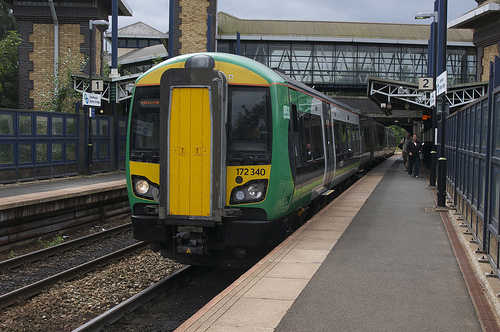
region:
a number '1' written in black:
[236, 168, 241, 175]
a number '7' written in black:
[238, 166, 244, 174]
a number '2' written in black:
[242, 166, 249, 175]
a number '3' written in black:
[249, 167, 255, 179]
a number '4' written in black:
[255, 168, 260, 178]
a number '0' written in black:
[261, 169, 267, 177]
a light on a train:
[228, 176, 271, 210]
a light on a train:
[126, 169, 163, 199]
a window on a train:
[223, 86, 273, 167]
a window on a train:
[129, 88, 159, 159]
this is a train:
[92, 72, 316, 161]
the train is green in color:
[271, 82, 292, 212]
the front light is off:
[228, 180, 264, 208]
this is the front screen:
[238, 93, 268, 150]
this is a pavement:
[388, 227, 435, 311]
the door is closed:
[321, 105, 327, 190]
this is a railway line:
[42, 226, 97, 321]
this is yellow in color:
[151, 90, 206, 261]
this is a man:
[405, 135, 420, 171]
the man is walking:
[403, 132, 421, 176]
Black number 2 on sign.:
[410, 66, 432, 102]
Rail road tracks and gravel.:
[1, 224, 138, 329]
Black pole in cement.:
[418, 144, 470, 235]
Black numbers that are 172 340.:
[222, 159, 274, 183]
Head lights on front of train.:
[101, 176, 278, 208]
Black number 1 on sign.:
[72, 68, 114, 97]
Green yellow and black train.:
[86, 55, 365, 263]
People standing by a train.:
[283, 125, 435, 197]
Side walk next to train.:
[240, 167, 435, 330]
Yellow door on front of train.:
[156, 102, 221, 224]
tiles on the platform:
[228, 287, 325, 329]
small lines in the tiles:
[216, 278, 282, 311]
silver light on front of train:
[234, 171, 288, 210]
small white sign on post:
[394, 71, 464, 102]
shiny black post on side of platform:
[421, 85, 477, 214]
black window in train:
[218, 73, 288, 202]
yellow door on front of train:
[152, 75, 247, 240]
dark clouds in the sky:
[276, 6, 376, 25]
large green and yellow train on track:
[86, 33, 375, 234]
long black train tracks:
[30, 198, 245, 329]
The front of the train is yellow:
[106, 42, 292, 234]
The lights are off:
[106, 161, 227, 233]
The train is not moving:
[87, 66, 244, 305]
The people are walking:
[375, 123, 484, 206]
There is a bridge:
[200, 10, 481, 118]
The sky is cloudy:
[231, 2, 464, 69]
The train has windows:
[268, 62, 457, 222]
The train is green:
[259, 66, 374, 267]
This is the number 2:
[415, 72, 454, 97]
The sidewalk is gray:
[335, 205, 489, 329]